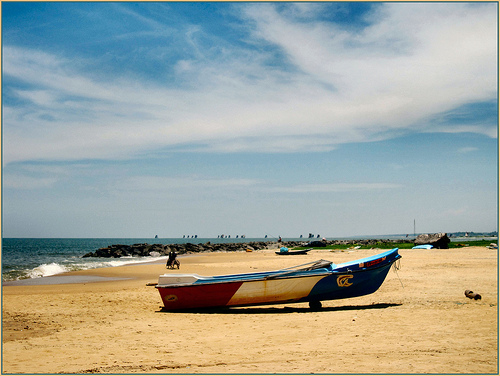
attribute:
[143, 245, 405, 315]
boat — red, white, blue, dirty, colorful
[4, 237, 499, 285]
water — blue, calm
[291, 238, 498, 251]
grass — green, short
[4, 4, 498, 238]
sky — blue, white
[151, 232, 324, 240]
boats — distant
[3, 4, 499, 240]
clouds — white, large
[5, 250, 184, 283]
waves — white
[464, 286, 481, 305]
log — brown, small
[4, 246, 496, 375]
sand — tan, damp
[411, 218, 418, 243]
mast — small, gray